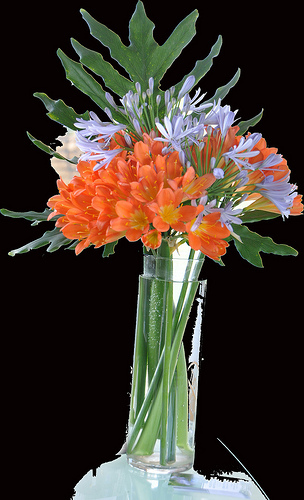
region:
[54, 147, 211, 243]
A moderate cluster of orange flowers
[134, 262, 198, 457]
Clear cylindrical see-through vase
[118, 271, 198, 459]
About six thick green stems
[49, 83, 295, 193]
A smaller cluster of white flowers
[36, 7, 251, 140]
Broad green leaves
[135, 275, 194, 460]
Vase filled with water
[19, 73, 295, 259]
An arrangement of flowers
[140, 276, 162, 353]
Some air bubbles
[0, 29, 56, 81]
Black background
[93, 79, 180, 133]
Flowers that have not blossomed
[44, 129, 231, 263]
orange flowers in a vase.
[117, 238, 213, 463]
a vase filled with green stems.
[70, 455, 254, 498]
a surface with a vase on it.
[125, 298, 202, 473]
water inside of a vase.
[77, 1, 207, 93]
green leaves on a flower.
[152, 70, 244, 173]
purple flowers in a vase.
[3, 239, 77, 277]
leaves on a flower.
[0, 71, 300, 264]
a bouquet filled with colorful flowers.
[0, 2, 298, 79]
green leaves in a bouquet of flowers.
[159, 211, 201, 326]
light coming from a opening.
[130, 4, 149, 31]
part of a leaf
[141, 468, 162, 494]
part of a glass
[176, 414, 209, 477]
edge of a glass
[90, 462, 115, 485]
part of an edge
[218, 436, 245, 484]
part of a line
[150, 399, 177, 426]
part of a stalk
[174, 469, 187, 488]
part of a glass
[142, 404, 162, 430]
part of a stem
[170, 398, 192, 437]
part of a plant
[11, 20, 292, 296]
vivid flowers and leaves against a black background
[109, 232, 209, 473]
narrow glass vase filled with green stems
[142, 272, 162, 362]
tiny white bubbles on the side of a stem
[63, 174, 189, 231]
orange flowers with yellow centers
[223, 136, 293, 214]
spiky white tubular flowers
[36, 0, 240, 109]
long and thin leaves reaching upward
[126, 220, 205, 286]
top of vase with narrowing opening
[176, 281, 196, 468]
reflection of side of vase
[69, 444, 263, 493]
circular and jagged reflection on surface under vase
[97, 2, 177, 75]
yellow spots on top leaf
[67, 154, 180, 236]
orange and yellow plant in vase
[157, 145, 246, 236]
orange and yellow and green plant in vase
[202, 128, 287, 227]
orange and yellow and green plant in vase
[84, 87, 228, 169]
orange and yellow and green plant in vase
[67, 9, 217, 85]
green leaves of plant in vase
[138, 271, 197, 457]
green plant stems in vase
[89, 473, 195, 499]
white material under vase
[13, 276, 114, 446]
black contrast with vase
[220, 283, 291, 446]
black contrast with vase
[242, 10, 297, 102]
black contrast with vase